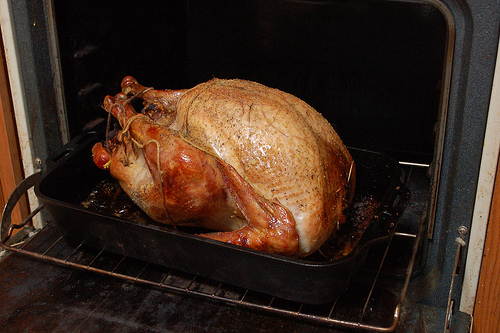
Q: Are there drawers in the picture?
A: No, there are no drawers.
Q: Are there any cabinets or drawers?
A: No, there are no drawers or cabinets.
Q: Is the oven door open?
A: Yes, the oven door is open.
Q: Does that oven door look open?
A: Yes, the oven door is open.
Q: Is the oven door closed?
A: No, the oven door is open.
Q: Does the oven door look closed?
A: No, the oven door is open.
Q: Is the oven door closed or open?
A: The oven door is open.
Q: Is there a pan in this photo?
A: Yes, there is a pan.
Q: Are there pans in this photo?
A: Yes, there is a pan.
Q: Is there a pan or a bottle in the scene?
A: Yes, there is a pan.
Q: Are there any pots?
A: No, there are no pots.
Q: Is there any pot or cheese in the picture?
A: No, there are no pots or cheese.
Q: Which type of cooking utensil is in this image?
A: The cooking utensil is a pan.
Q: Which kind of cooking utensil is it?
A: The cooking utensil is a pan.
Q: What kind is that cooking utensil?
A: This is a pan.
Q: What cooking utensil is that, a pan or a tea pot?
A: This is a pan.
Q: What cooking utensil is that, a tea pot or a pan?
A: This is a pan.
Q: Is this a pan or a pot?
A: This is a pan.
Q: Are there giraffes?
A: No, there are no giraffes.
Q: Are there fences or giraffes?
A: No, there are no giraffes or fences.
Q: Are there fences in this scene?
A: No, there are no fences.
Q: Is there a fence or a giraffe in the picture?
A: No, there are no fences or giraffes.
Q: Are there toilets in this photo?
A: No, there are no toilets.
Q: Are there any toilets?
A: No, there are no toilets.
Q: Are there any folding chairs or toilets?
A: No, there are no toilets or folding chairs.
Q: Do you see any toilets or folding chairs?
A: No, there are no toilets or folding chairs.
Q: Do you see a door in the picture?
A: Yes, there is a door.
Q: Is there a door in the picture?
A: Yes, there is a door.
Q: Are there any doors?
A: Yes, there is a door.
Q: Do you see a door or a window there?
A: Yes, there is a door.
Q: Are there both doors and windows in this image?
A: No, there is a door but no windows.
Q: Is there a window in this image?
A: No, there are no windows.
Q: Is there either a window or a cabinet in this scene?
A: No, there are no windows or cabinets.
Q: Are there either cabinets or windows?
A: No, there are no windows or cabinets.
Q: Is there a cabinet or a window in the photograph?
A: No, there are no windows or cabinets.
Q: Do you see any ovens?
A: Yes, there is an oven.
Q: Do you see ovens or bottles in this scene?
A: Yes, there is an oven.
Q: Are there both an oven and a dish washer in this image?
A: No, there is an oven but no dishwashers.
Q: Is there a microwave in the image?
A: No, there are no microwaves.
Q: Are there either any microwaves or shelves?
A: No, there are no microwaves or shelves.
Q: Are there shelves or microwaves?
A: No, there are no microwaves or shelves.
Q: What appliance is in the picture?
A: The appliance is an oven.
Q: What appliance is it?
A: The appliance is an oven.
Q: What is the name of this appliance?
A: That is an oven.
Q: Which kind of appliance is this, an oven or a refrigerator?
A: That is an oven.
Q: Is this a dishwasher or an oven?
A: This is an oven.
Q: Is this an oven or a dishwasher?
A: This is an oven.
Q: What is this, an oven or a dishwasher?
A: This is an oven.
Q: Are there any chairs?
A: No, there are no chairs.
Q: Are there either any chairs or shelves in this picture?
A: No, there are no chairs or shelves.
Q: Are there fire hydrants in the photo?
A: No, there are no fire hydrants.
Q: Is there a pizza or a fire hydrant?
A: No, there are no fire hydrants or pizzas.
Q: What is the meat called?
A: The meat is chicken.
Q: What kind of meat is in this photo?
A: The meat is chicken.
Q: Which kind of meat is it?
A: The meat is chicken.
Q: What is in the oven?
A: The chicken is in the oven.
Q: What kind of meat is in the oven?
A: The meat is chicken.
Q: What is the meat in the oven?
A: The meat is chicken.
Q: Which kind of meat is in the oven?
A: The meat is chicken.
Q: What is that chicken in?
A: The chicken is in the oven.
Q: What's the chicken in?
A: The chicken is in the oven.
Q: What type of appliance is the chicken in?
A: The chicken is in the oven.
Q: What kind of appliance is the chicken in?
A: The chicken is in the oven.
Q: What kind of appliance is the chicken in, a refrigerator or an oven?
A: The chicken is in an oven.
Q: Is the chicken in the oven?
A: Yes, the chicken is in the oven.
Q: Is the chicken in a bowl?
A: No, the chicken is in the oven.